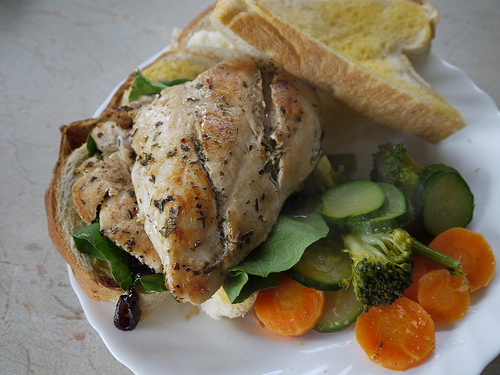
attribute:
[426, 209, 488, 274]
carrot — cooked, orange, sliced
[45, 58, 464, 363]
plate — white, light, chicken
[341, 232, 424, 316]
broccoli — pieces, green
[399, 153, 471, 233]
cucumber — green, sliced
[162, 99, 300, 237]
breast — chicken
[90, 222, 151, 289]
zucchini — slices, steamed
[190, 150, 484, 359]
vegetable — cooked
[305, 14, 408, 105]
toast — buttered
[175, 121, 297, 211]
chicken — pan, large, brown, herb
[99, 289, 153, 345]
cranberry — single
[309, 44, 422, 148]
bread — buttered, butter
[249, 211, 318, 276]
lettuce — green